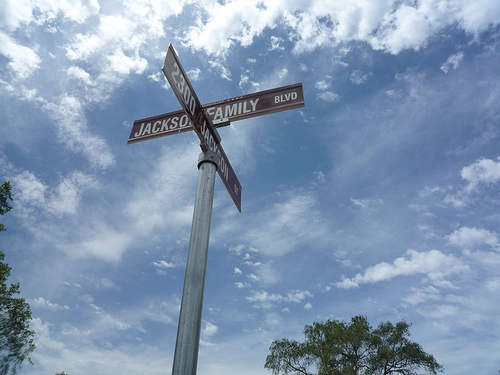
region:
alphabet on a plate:
[131, 119, 146, 139]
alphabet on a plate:
[155, 114, 163, 135]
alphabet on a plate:
[170, 110, 180, 127]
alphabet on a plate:
[226, 96, 237, 123]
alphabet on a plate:
[236, 77, 245, 122]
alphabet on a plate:
[246, 85, 261, 115]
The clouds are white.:
[339, 1, 496, 43]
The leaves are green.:
[272, 319, 437, 373]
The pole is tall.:
[167, 167, 222, 373]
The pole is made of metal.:
[172, 159, 219, 374]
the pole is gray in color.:
[172, 156, 223, 372]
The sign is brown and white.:
[149, 44, 256, 209]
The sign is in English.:
[157, 39, 252, 212]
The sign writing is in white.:
[127, 84, 312, 142]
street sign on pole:
[109, 25, 326, 259]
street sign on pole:
[113, 56, 300, 241]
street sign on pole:
[112, 44, 312, 236]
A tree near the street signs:
[266, 318, 441, 374]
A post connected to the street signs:
[170, 154, 221, 374]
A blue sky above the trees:
[0, 0, 497, 374]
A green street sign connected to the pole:
[162, 44, 242, 208]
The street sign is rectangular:
[159, 42, 242, 209]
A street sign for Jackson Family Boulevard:
[128, 84, 304, 141]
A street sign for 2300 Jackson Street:
[158, 44, 243, 208]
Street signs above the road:
[126, 44, 306, 210]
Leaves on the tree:
[263, 316, 440, 374]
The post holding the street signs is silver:
[169, 151, 221, 374]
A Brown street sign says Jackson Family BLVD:
[121, 80, 313, 146]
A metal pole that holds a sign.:
[165, 146, 223, 373]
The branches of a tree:
[258, 312, 450, 374]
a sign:
[158, 47, 291, 203]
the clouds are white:
[358, 253, 458, 301]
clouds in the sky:
[383, 220, 477, 301]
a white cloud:
[390, 250, 450, 283]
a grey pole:
[178, 296, 200, 373]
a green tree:
[310, 325, 375, 353]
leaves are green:
[1, 303, 28, 373]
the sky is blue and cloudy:
[333, 143, 390, 197]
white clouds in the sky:
[325, 6, 438, 45]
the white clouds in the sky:
[96, 24, 148, 80]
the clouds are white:
[0, 0, 496, 372]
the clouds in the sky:
[0, 0, 496, 371]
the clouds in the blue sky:
[1, 0, 497, 372]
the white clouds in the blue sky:
[0, 0, 497, 372]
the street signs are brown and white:
[124, 42, 304, 213]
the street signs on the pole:
[126, 43, 304, 374]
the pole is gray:
[173, 150, 215, 373]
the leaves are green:
[0, 179, 445, 374]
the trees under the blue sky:
[0, 0, 497, 374]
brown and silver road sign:
[123, 40, 304, 371]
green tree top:
[265, 313, 446, 373]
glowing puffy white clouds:
[6, 0, 291, 83]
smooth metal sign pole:
[168, 160, 216, 372]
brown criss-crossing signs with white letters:
[125, 42, 305, 212]